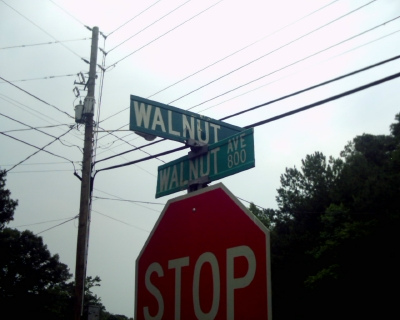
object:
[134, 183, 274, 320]
sign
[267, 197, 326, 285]
tree branch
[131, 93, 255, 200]
sign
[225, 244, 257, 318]
p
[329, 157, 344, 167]
branch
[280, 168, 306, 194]
tree branch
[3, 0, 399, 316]
sky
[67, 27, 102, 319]
electric pole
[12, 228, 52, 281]
tree branch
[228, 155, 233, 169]
white 8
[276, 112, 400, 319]
trees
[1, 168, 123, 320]
trees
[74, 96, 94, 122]
transformer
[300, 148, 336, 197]
tree branch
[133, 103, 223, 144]
walnut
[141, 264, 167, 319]
s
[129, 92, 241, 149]
sign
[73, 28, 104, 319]
post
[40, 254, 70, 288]
branch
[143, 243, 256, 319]
stop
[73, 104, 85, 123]
bucket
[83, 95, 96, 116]
bucket